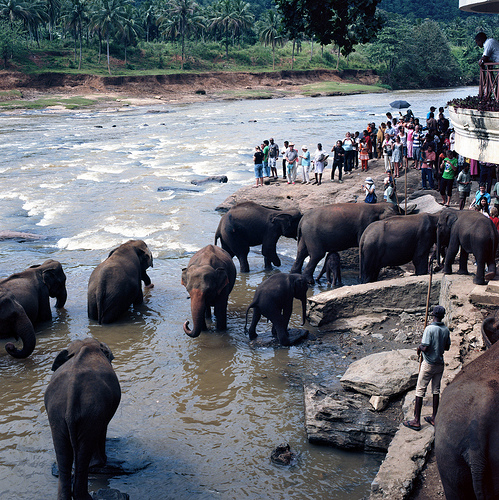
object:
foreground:
[0, 180, 499, 498]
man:
[467, 181, 491, 211]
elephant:
[314, 250, 344, 286]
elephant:
[286, 200, 402, 285]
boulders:
[269, 439, 296, 466]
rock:
[368, 113, 376, 116]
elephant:
[215, 201, 302, 274]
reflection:
[170, 331, 240, 428]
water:
[0, 83, 481, 500]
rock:
[143, 123, 149, 126]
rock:
[160, 122, 166, 125]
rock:
[93, 125, 103, 128]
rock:
[111, 124, 117, 128]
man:
[474, 32, 499, 99]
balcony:
[445, 98, 499, 164]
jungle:
[1, 0, 497, 91]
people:
[251, 144, 266, 188]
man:
[284, 140, 299, 185]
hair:
[432, 305, 447, 320]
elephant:
[87, 237, 155, 326]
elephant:
[0, 283, 38, 361]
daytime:
[0, 0, 499, 500]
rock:
[400, 311, 410, 319]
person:
[310, 141, 330, 186]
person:
[298, 144, 311, 185]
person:
[331, 139, 346, 184]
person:
[383, 169, 397, 203]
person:
[359, 137, 370, 172]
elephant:
[432, 315, 499, 500]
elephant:
[179, 243, 237, 339]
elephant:
[434, 207, 499, 286]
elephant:
[358, 210, 447, 285]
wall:
[440, 105, 499, 165]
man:
[401, 304, 452, 432]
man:
[438, 149, 458, 207]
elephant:
[243, 270, 312, 348]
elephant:
[43, 335, 123, 500]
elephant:
[0, 257, 68, 341]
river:
[8, 124, 189, 223]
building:
[445, 0, 499, 166]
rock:
[393, 328, 408, 341]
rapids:
[54, 214, 162, 252]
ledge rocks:
[367, 394, 392, 411]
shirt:
[420, 321, 452, 366]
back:
[48, 346, 106, 411]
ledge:
[303, 278, 441, 452]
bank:
[213, 155, 499, 500]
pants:
[416, 359, 446, 399]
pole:
[418, 242, 437, 373]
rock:
[190, 175, 228, 187]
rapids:
[0, 189, 58, 229]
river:
[0, 85, 483, 500]